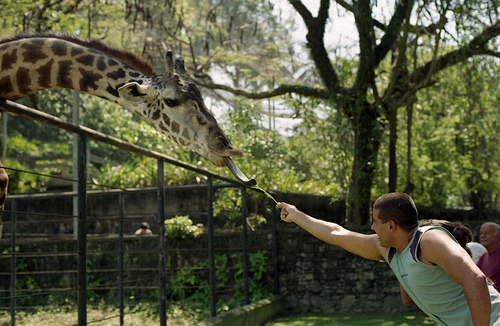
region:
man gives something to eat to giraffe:
[74, 57, 498, 324]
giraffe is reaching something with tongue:
[111, 27, 308, 232]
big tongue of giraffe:
[200, 113, 258, 193]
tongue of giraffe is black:
[210, 139, 268, 197]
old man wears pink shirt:
[466, 208, 498, 296]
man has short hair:
[267, 171, 498, 323]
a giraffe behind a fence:
[3, 19, 314, 316]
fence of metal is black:
[7, 102, 293, 322]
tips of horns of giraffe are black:
[116, 36, 259, 193]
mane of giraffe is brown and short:
[5, 21, 164, 78]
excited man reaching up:
[276, 188, 498, 324]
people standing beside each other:
[276, 195, 498, 322]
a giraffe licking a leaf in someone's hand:
[106, 42, 288, 221]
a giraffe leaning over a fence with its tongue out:
[0, 31, 268, 211]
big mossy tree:
[221, 7, 426, 226]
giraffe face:
[120, 47, 259, 204]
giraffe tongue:
[206, 138, 276, 220]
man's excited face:
[354, 182, 430, 271]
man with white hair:
[473, 217, 499, 255]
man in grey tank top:
[342, 187, 464, 323]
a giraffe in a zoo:
[9, 20, 256, 202]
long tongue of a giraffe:
[218, 148, 256, 188]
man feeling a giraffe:
[161, 56, 312, 257]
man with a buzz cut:
[361, 185, 431, 260]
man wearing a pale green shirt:
[373, 243, 493, 323]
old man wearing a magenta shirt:
[471, 220, 498, 282]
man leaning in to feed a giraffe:
[113, 56, 483, 319]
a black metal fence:
[16, 165, 244, 318]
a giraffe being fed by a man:
[16, 22, 466, 253]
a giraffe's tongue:
[214, 147, 262, 188]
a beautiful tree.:
[233, 0, 485, 194]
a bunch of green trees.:
[230, 21, 497, 193]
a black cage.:
[1, 147, 231, 324]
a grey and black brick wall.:
[273, 243, 372, 322]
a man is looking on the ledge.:
[125, 205, 160, 252]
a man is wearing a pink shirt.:
[486, 260, 499, 279]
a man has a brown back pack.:
[423, 214, 483, 251]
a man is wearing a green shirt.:
[413, 267, 460, 323]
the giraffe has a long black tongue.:
[225, 157, 257, 188]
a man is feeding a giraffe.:
[1, 2, 483, 321]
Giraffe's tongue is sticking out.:
[158, 75, 260, 194]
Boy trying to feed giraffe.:
[232, 168, 430, 266]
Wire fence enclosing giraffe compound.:
[129, 27, 258, 304]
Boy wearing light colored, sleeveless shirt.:
[355, 173, 451, 295]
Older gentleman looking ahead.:
[468, 215, 498, 276]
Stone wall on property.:
[281, 190, 330, 321]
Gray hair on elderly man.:
[474, 216, 499, 267]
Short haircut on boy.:
[356, 181, 421, 267]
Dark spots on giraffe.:
[97, 31, 184, 116]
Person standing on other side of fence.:
[126, 212, 169, 256]